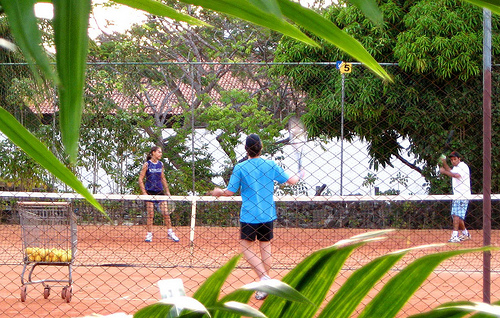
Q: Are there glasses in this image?
A: No, there are no glasses.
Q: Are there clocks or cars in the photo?
A: No, there are no clocks or cars.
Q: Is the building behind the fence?
A: Yes, the building is behind the fence.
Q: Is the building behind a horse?
A: No, the building is behind the fence.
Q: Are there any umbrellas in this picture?
A: No, there are no umbrellas.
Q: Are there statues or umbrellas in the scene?
A: No, there are no umbrellas or statues.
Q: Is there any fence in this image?
A: Yes, there is a fence.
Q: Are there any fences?
A: Yes, there is a fence.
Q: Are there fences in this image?
A: Yes, there is a fence.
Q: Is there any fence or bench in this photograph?
A: Yes, there is a fence.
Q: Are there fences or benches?
A: Yes, there is a fence.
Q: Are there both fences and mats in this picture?
A: No, there is a fence but no mats.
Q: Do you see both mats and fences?
A: No, there is a fence but no mats.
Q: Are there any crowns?
A: No, there are no crowns.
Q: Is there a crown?
A: No, there are no crowns.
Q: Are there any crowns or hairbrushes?
A: No, there are no crowns or hairbrushes.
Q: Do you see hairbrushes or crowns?
A: No, there are no crowns or hairbrushes.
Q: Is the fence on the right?
A: Yes, the fence is on the right of the image.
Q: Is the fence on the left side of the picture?
A: No, the fence is on the right of the image.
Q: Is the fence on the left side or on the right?
A: The fence is on the right of the image.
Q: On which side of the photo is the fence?
A: The fence is on the right of the image.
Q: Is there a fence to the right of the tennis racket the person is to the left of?
A: Yes, there is a fence to the right of the racket.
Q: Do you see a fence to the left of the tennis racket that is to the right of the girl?
A: No, the fence is to the right of the racket.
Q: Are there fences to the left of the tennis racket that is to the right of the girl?
A: No, the fence is to the right of the racket.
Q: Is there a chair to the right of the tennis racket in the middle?
A: No, there is a fence to the right of the racket.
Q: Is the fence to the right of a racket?
A: Yes, the fence is to the right of a racket.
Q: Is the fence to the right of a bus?
A: No, the fence is to the right of a racket.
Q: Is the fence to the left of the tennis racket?
A: No, the fence is to the right of the tennis racket.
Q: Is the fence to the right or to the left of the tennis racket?
A: The fence is to the right of the tennis racket.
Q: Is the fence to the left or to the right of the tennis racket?
A: The fence is to the right of the tennis racket.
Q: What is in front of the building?
A: The fence is in front of the building.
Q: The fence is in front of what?
A: The fence is in front of the building.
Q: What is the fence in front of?
A: The fence is in front of the building.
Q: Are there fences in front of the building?
A: Yes, there is a fence in front of the building.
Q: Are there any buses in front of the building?
A: No, there is a fence in front of the building.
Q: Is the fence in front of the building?
A: Yes, the fence is in front of the building.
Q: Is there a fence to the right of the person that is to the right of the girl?
A: Yes, there is a fence to the right of the person.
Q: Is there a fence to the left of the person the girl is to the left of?
A: No, the fence is to the right of the person.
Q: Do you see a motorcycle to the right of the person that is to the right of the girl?
A: No, there is a fence to the right of the person.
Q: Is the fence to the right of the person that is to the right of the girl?
A: Yes, the fence is to the right of the person.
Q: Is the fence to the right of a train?
A: No, the fence is to the right of the person.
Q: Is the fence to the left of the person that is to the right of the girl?
A: No, the fence is to the right of the person.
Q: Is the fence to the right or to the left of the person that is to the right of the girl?
A: The fence is to the right of the person.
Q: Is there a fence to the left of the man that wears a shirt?
A: Yes, there is a fence to the left of the man.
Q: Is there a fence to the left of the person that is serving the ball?
A: Yes, there is a fence to the left of the man.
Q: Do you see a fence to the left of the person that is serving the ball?
A: Yes, there is a fence to the left of the man.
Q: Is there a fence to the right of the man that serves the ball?
A: No, the fence is to the left of the man.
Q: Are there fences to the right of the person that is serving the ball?
A: No, the fence is to the left of the man.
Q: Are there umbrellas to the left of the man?
A: No, there is a fence to the left of the man.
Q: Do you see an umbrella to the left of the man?
A: No, there is a fence to the left of the man.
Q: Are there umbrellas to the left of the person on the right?
A: No, there is a fence to the left of the man.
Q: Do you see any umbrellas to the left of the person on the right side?
A: No, there is a fence to the left of the man.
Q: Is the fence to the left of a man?
A: Yes, the fence is to the left of a man.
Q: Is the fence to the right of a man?
A: No, the fence is to the left of a man.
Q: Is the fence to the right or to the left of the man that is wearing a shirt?
A: The fence is to the left of the man.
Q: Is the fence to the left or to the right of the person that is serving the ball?
A: The fence is to the left of the man.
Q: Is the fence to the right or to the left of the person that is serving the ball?
A: The fence is to the left of the man.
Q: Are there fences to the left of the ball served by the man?
A: Yes, there is a fence to the left of the ball.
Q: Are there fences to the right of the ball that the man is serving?
A: No, the fence is to the left of the ball.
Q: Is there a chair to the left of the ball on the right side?
A: No, there is a fence to the left of the ball.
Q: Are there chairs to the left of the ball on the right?
A: No, there is a fence to the left of the ball.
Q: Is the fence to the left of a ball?
A: Yes, the fence is to the left of a ball.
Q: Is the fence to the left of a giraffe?
A: No, the fence is to the left of a ball.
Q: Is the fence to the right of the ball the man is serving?
A: No, the fence is to the left of the ball.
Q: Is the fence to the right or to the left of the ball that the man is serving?
A: The fence is to the left of the ball.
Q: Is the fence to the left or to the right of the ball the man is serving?
A: The fence is to the left of the ball.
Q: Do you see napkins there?
A: No, there are no napkins.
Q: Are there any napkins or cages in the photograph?
A: No, there are no napkins or cages.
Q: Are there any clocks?
A: No, there are no clocks.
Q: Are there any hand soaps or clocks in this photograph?
A: No, there are no clocks or hand soaps.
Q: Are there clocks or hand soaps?
A: No, there are no clocks or hand soaps.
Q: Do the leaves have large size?
A: Yes, the leaves are large.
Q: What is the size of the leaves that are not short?
A: The leaves are large.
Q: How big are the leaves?
A: The leaves are large.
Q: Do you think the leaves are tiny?
A: No, the leaves are large.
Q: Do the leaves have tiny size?
A: No, the leaves are large.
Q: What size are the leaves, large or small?
A: The leaves are large.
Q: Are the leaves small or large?
A: The leaves are large.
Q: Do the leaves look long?
A: Yes, the leaves are long.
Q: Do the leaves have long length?
A: Yes, the leaves are long.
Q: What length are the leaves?
A: The leaves are long.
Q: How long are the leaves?
A: The leaves are long.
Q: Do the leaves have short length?
A: No, the leaves are long.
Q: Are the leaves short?
A: No, the leaves are long.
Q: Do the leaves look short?
A: No, the leaves are long.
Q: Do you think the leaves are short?
A: No, the leaves are long.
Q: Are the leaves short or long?
A: The leaves are long.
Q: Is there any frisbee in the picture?
A: No, there are no frisbees.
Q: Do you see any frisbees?
A: No, there are no frisbees.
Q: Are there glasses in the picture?
A: No, there are no glasses.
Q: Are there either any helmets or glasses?
A: No, there are no glasses or helmets.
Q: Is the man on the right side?
A: Yes, the man is on the right of the image.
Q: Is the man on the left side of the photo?
A: No, the man is on the right of the image.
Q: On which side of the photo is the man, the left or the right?
A: The man is on the right of the image.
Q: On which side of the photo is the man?
A: The man is on the right of the image.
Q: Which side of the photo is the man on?
A: The man is on the right of the image.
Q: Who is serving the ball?
A: The man is serving the ball.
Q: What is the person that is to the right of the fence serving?
A: The man is serving the ball.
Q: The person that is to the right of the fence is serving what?
A: The man is serving the ball.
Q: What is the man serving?
A: The man is serving the ball.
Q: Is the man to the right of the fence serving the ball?
A: Yes, the man is serving the ball.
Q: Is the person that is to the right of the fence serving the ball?
A: Yes, the man is serving the ball.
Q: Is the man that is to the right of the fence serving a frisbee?
A: No, the man is serving the ball.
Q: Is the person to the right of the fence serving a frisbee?
A: No, the man is serving the ball.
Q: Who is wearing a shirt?
A: The man is wearing a shirt.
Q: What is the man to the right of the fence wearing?
A: The man is wearing a shirt.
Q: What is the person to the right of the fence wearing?
A: The man is wearing a shirt.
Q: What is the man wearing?
A: The man is wearing a shirt.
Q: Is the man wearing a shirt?
A: Yes, the man is wearing a shirt.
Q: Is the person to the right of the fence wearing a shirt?
A: Yes, the man is wearing a shirt.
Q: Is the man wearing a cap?
A: No, the man is wearing a shirt.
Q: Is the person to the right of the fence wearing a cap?
A: No, the man is wearing a shirt.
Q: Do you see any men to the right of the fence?
A: Yes, there is a man to the right of the fence.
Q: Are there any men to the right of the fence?
A: Yes, there is a man to the right of the fence.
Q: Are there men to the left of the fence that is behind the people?
A: No, the man is to the right of the fence.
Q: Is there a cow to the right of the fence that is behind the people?
A: No, there is a man to the right of the fence.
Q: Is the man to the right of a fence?
A: Yes, the man is to the right of a fence.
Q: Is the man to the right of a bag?
A: No, the man is to the right of a fence.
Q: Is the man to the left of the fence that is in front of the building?
A: No, the man is to the right of the fence.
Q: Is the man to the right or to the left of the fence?
A: The man is to the right of the fence.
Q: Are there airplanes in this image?
A: No, there are no airplanes.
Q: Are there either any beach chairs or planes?
A: No, there are no planes or beach chairs.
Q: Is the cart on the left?
A: Yes, the cart is on the left of the image.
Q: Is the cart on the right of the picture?
A: No, the cart is on the left of the image.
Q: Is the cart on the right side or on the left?
A: The cart is on the left of the image.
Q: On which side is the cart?
A: The cart is on the left of the image.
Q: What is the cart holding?
A: The cart is holding the balls.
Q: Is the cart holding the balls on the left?
A: Yes, the cart is holding the balls.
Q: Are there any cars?
A: No, there are no cars.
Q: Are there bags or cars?
A: No, there are no cars or bags.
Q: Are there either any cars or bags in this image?
A: No, there are no cars or bags.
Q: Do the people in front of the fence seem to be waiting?
A: No, the people are playing.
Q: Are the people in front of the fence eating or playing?
A: The people are playing.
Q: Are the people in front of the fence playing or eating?
A: The people are playing.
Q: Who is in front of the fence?
A: The people are in front of the fence.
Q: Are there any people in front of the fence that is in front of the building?
A: Yes, there are people in front of the fence.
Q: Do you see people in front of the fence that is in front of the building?
A: Yes, there are people in front of the fence.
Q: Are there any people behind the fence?
A: No, the people are in front of the fence.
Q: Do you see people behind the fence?
A: No, the people are in front of the fence.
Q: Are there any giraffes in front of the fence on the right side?
A: No, there are people in front of the fence.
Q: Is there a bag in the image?
A: No, there are no bags.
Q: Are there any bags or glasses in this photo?
A: No, there are no bags or glasses.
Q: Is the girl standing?
A: Yes, the girl is standing.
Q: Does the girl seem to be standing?
A: Yes, the girl is standing.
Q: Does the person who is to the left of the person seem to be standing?
A: Yes, the girl is standing.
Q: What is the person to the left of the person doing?
A: The girl is standing.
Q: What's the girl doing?
A: The girl is standing.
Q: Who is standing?
A: The girl is standing.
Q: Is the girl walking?
A: No, the girl is standing.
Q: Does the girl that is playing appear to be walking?
A: No, the girl is standing.